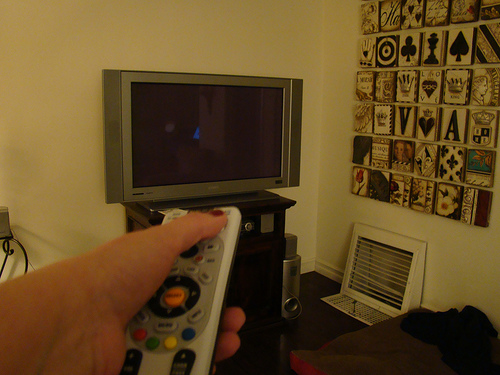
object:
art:
[349, 165, 369, 197]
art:
[388, 136, 416, 173]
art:
[436, 144, 466, 181]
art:
[434, 180, 462, 220]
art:
[374, 34, 397, 67]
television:
[91, 63, 312, 210]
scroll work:
[0, 238, 27, 280]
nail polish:
[205, 201, 229, 231]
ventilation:
[348, 229, 425, 314]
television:
[63, 50, 337, 213]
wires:
[1, 236, 28, 282]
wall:
[0, 0, 320, 280]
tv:
[109, 75, 299, 184]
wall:
[7, 6, 336, 119]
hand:
[2, 200, 228, 372]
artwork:
[348, 0, 499, 228]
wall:
[314, 0, 499, 332]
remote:
[122, 206, 239, 318]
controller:
[97, 196, 253, 373]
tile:
[391, 102, 417, 141]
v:
[398, 105, 410, 132]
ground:
[319, 105, 359, 142]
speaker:
[280, 256, 305, 323]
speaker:
[287, 230, 298, 255]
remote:
[119, 193, 246, 373]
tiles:
[351, 70, 373, 99]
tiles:
[413, 105, 439, 142]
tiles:
[430, 182, 462, 219]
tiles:
[417, 27, 447, 68]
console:
[274, 222, 324, 351]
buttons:
[109, 322, 196, 353]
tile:
[442, 25, 474, 65]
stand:
[123, 189, 312, 373]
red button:
[129, 326, 148, 340]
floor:
[278, 312, 335, 344]